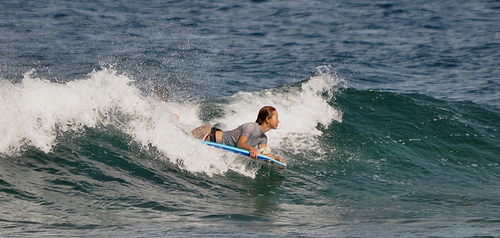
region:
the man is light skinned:
[270, 113, 281, 130]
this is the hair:
[258, 110, 269, 119]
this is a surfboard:
[210, 141, 240, 162]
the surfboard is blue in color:
[217, 142, 240, 152]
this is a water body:
[339, 99, 448, 223]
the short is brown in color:
[192, 118, 209, 141]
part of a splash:
[301, 115, 326, 144]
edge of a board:
[253, 160, 270, 188]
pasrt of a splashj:
[100, 103, 141, 143]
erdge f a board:
[211, 114, 257, 177]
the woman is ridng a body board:
[184, 97, 300, 176]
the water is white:
[18, 89, 105, 119]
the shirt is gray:
[224, 125, 264, 143]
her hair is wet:
[256, 104, 276, 121]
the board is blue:
[207, 137, 289, 177]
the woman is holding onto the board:
[237, 134, 286, 175]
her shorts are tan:
[196, 119, 212, 146]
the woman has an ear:
[261, 114, 273, 128]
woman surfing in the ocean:
[186, 89, 296, 164]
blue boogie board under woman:
[209, 141, 294, 162]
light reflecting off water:
[200, 171, 314, 226]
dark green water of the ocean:
[308, 194, 383, 234]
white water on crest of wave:
[292, 77, 352, 137]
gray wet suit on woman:
[231, 121, 260, 153]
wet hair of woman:
[257, 104, 273, 123]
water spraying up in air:
[90, 46, 172, 81]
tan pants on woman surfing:
[193, 122, 215, 145]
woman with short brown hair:
[255, 101, 283, 132]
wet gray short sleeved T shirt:
[223, 122, 265, 154]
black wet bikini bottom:
[199, 124, 221, 143]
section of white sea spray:
[3, 69, 129, 156]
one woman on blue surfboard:
[191, 104, 293, 171]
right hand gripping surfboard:
[240, 147, 264, 162]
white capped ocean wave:
[232, 77, 337, 104]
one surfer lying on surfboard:
[125, 92, 343, 190]